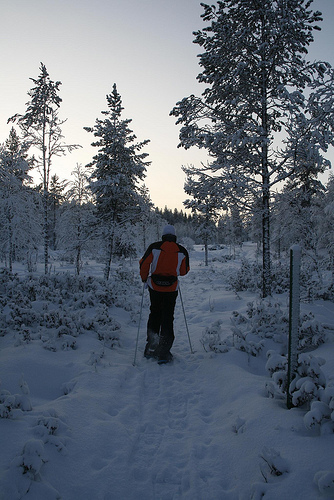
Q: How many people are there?
A: One.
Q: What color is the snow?
A: White.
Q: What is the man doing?
A: Skiing.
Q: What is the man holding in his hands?
A: Trekking poles.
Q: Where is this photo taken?
A: On a ski slope.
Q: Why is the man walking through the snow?
A: Because he is skiing.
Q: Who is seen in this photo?
A: A man.